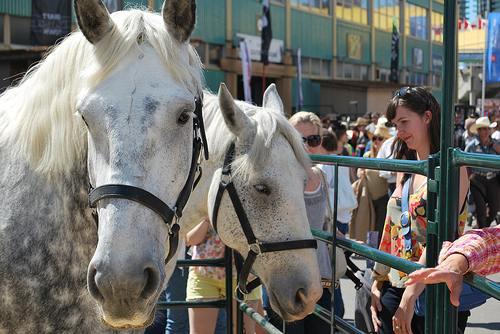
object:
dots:
[142, 97, 159, 113]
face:
[76, 29, 197, 326]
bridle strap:
[84, 74, 210, 264]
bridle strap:
[208, 140, 317, 301]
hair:
[0, 9, 211, 179]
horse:
[0, 0, 201, 333]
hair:
[201, 91, 320, 180]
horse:
[180, 82, 327, 325]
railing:
[227, 142, 500, 334]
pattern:
[0, 150, 94, 334]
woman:
[257, 109, 334, 333]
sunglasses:
[296, 134, 323, 147]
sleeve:
[440, 224, 500, 276]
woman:
[361, 84, 475, 334]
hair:
[385, 85, 443, 162]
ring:
[165, 212, 182, 235]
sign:
[347, 33, 365, 60]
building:
[0, 0, 461, 137]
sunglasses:
[391, 86, 436, 107]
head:
[383, 86, 444, 153]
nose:
[82, 223, 170, 330]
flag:
[256, 1, 274, 68]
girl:
[187, 215, 261, 333]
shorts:
[184, 265, 263, 302]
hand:
[401, 265, 463, 308]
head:
[63, 1, 208, 330]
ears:
[158, 0, 200, 44]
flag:
[483, 11, 500, 83]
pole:
[257, 6, 274, 111]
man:
[463, 115, 499, 228]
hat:
[469, 116, 498, 134]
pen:
[0, 106, 499, 334]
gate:
[234, 140, 438, 334]